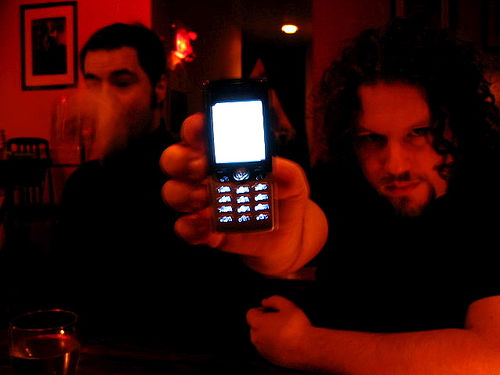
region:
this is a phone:
[207, 70, 272, 220]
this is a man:
[328, 83, 454, 371]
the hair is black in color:
[440, 109, 482, 169]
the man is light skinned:
[325, 337, 385, 362]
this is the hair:
[440, 45, 475, 81]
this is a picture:
[15, 7, 70, 77]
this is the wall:
[6, 100, 31, 125]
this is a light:
[276, 20, 306, 40]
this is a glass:
[20, 311, 95, 356]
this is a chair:
[5, 135, 65, 163]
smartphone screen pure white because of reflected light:
[211, 100, 263, 161]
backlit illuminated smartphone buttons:
[215, 166, 270, 231]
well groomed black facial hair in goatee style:
[368, 172, 438, 223]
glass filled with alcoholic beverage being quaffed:
[50, 81, 117, 166]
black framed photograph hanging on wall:
[18, 4, 77, 92]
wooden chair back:
[3, 132, 53, 199]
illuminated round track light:
[279, 22, 299, 36]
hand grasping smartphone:
[162, 74, 302, 274]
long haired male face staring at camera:
[308, 23, 498, 221]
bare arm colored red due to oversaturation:
[247, 288, 498, 373]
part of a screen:
[228, 92, 258, 124]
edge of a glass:
[39, 323, 65, 345]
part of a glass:
[36, 335, 63, 364]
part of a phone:
[253, 218, 323, 307]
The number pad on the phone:
[214, 181, 271, 223]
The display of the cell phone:
[212, 98, 262, 161]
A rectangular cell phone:
[208, 95, 273, 231]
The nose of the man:
[386, 138, 407, 175]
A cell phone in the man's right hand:
[166, 113, 305, 257]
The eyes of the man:
[358, 124, 436, 149]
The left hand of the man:
[245, 289, 310, 364]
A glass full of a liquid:
[1, 307, 78, 374]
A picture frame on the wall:
[18, 5, 78, 87]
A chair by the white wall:
[0, 138, 51, 205]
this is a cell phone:
[205, 78, 266, 230]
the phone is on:
[212, 101, 260, 162]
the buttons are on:
[216, 182, 266, 222]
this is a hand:
[401, 328, 475, 373]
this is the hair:
[428, 60, 488, 127]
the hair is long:
[435, 47, 478, 120]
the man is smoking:
[74, 98, 124, 144]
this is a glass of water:
[10, 307, 76, 373]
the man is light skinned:
[419, 333, 466, 367]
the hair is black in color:
[114, 22, 141, 42]